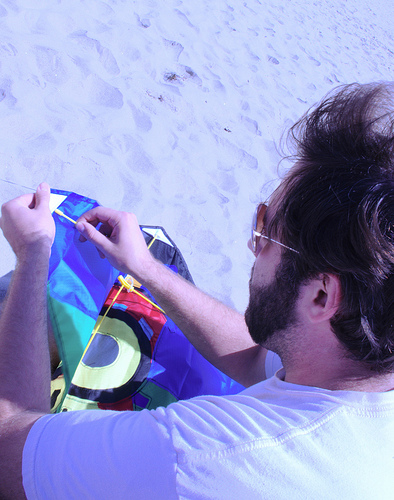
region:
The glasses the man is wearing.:
[250, 198, 298, 268]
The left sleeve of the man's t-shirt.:
[28, 394, 177, 494]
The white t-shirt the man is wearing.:
[36, 389, 392, 498]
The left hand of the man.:
[1, 179, 62, 243]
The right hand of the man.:
[78, 206, 143, 265]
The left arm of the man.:
[1, 245, 56, 497]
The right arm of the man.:
[145, 249, 282, 379]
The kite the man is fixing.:
[11, 177, 235, 400]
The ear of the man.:
[309, 270, 341, 326]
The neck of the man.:
[287, 327, 391, 395]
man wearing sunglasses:
[196, 147, 388, 389]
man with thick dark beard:
[198, 196, 348, 364]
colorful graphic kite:
[18, 163, 247, 453]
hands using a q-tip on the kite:
[29, 172, 143, 258]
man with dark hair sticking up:
[218, 101, 388, 350]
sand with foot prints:
[59, 112, 288, 259]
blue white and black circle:
[55, 295, 168, 400]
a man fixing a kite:
[7, 111, 392, 489]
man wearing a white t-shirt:
[22, 315, 382, 489]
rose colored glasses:
[235, 181, 300, 265]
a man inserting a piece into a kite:
[3, 170, 392, 480]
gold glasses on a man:
[252, 200, 302, 271]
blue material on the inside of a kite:
[52, 244, 90, 295]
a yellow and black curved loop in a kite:
[69, 307, 149, 400]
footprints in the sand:
[67, 26, 136, 135]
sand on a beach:
[84, 19, 288, 172]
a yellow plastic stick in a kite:
[41, 202, 95, 240]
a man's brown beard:
[242, 271, 298, 350]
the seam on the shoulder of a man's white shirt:
[169, 400, 351, 475]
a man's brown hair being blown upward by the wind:
[309, 73, 392, 156]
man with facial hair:
[229, 113, 383, 383]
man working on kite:
[14, 150, 342, 439]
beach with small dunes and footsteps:
[6, 12, 276, 191]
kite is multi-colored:
[20, 172, 230, 425]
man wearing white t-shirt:
[12, 351, 388, 492]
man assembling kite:
[6, 174, 250, 433]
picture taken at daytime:
[4, 11, 378, 481]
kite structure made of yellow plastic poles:
[33, 192, 217, 417]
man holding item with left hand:
[0, 168, 98, 462]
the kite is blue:
[52, 211, 239, 395]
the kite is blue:
[78, 260, 165, 352]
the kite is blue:
[86, 217, 207, 347]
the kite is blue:
[67, 274, 140, 364]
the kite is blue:
[79, 269, 204, 425]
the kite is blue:
[70, 310, 281, 441]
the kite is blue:
[51, 220, 147, 341]